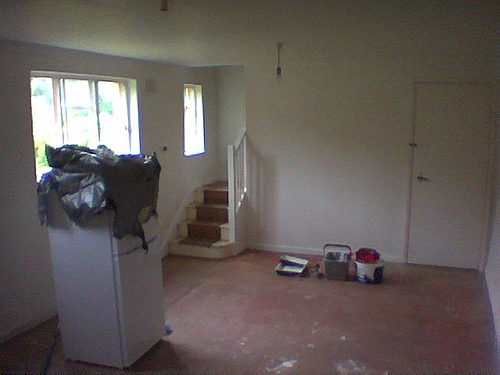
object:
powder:
[265, 358, 298, 374]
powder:
[306, 343, 316, 349]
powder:
[334, 358, 367, 373]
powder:
[240, 342, 246, 346]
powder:
[339, 336, 346, 340]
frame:
[25, 68, 142, 181]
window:
[30, 70, 66, 187]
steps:
[194, 182, 238, 207]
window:
[95, 73, 133, 158]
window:
[58, 75, 101, 151]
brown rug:
[176, 190, 232, 248]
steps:
[183, 202, 236, 222]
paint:
[328, 250, 350, 260]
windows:
[193, 85, 207, 157]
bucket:
[349, 246, 385, 285]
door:
[404, 81, 497, 274]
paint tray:
[273, 253, 310, 277]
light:
[270, 67, 287, 89]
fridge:
[45, 163, 166, 370]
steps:
[168, 238, 240, 262]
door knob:
[414, 174, 428, 183]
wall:
[188, 0, 499, 272]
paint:
[264, 355, 298, 374]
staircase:
[168, 180, 252, 261]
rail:
[226, 126, 250, 256]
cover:
[33, 143, 163, 256]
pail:
[320, 242, 352, 282]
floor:
[0, 246, 499, 374]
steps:
[177, 217, 232, 242]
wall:
[0, 39, 222, 344]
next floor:
[195, 176, 235, 191]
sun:
[27, 76, 143, 182]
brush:
[273, 253, 308, 277]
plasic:
[36, 142, 164, 255]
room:
[0, 0, 498, 374]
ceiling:
[0, 0, 499, 66]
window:
[179, 82, 197, 158]